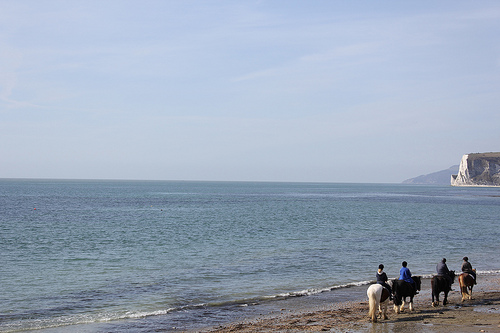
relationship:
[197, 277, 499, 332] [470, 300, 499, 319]
sand has puddle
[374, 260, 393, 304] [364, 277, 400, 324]
person riding horse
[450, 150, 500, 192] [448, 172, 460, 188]
mountain next to cliff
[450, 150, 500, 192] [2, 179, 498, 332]
mountain on side of ocean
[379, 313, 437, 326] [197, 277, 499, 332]
shadow reflected on sand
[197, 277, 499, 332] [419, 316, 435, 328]
sand has mark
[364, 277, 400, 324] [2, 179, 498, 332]
horse near ocean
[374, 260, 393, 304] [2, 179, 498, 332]
person near ocean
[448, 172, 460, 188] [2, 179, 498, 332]
cliff near ocean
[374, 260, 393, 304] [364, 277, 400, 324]
person on top of horse